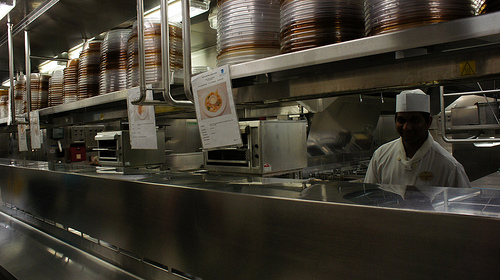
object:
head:
[394, 89, 434, 143]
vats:
[297, 159, 377, 182]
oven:
[91, 129, 168, 169]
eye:
[411, 118, 421, 122]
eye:
[397, 117, 405, 121]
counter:
[0, 149, 500, 280]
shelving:
[0, 0, 500, 117]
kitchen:
[0, 0, 500, 278]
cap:
[394, 89, 431, 114]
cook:
[362, 87, 473, 189]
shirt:
[363, 130, 473, 189]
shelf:
[180, 0, 498, 95]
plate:
[201, 90, 226, 117]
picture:
[197, 88, 231, 117]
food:
[206, 89, 220, 112]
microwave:
[202, 118, 309, 176]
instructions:
[189, 62, 243, 149]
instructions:
[125, 83, 158, 150]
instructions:
[29, 110, 41, 149]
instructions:
[15, 114, 28, 151]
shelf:
[5, 0, 193, 128]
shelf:
[0, 157, 500, 279]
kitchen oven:
[202, 118, 317, 178]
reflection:
[344, 176, 455, 224]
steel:
[2, 156, 500, 279]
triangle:
[460, 59, 474, 77]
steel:
[283, 54, 498, 99]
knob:
[251, 139, 261, 168]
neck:
[400, 133, 435, 158]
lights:
[0, 0, 212, 85]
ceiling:
[0, 2, 222, 88]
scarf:
[395, 129, 433, 165]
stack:
[214, 0, 280, 67]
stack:
[121, 19, 185, 90]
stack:
[78, 41, 98, 98]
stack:
[48, 71, 64, 105]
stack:
[279, 1, 361, 54]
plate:
[217, 42, 283, 52]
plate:
[277, 19, 362, 29]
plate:
[73, 65, 100, 74]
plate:
[129, 54, 187, 58]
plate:
[47, 85, 63, 90]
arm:
[440, 161, 471, 187]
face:
[396, 113, 425, 139]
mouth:
[403, 133, 415, 139]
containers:
[99, 26, 131, 96]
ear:
[427, 116, 434, 128]